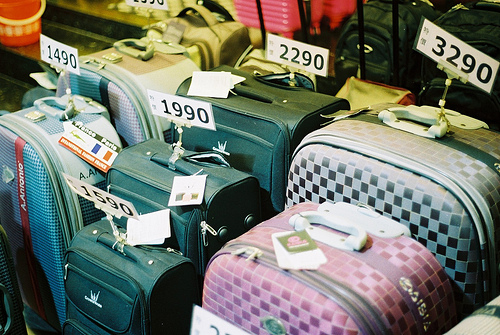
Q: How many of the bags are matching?
A: Three.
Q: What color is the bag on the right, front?
A: Purple and pink checks.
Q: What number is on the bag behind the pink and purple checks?
A: 3290.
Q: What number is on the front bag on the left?
A: 1490.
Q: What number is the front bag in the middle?
A: 1590.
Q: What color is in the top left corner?
A: Orange.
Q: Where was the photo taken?
A: At a luggage store.